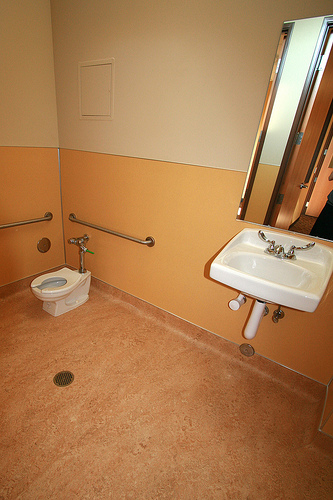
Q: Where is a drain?
A: On the floor.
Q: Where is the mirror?
A: On the wall.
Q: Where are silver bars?
A: On the wall.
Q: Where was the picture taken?
A: In a bathroom.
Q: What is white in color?
A: Sink.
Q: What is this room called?
A: Bathroom.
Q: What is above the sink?
A: A mirror.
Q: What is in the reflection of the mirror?
A: A door.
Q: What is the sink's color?
A: White.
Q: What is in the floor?
A: A drain.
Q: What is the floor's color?
A: Tan.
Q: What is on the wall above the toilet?
A: A silver rail.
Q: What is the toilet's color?
A: White.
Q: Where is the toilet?
A: On the left side.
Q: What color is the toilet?
A: White.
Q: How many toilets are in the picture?
A: One.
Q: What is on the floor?
A: Drain cover.